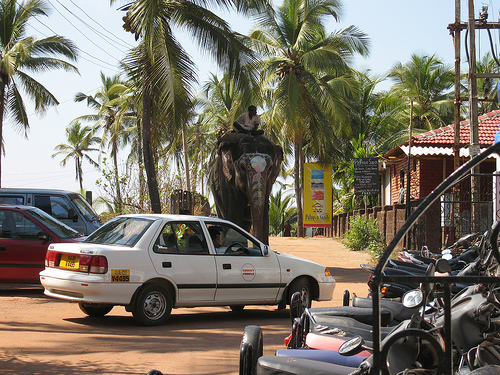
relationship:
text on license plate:
[63, 259, 77, 269] [57, 255, 81, 269]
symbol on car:
[238, 257, 260, 283] [48, 211, 340, 324]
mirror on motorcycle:
[399, 286, 434, 319] [224, 249, 472, 369]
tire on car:
[133, 281, 178, 328] [24, 205, 346, 333]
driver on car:
[204, 225, 235, 252] [48, 211, 340, 324]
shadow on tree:
[145, 320, 235, 370] [333, 250, 363, 282]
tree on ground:
[333, 250, 363, 282] [16, 320, 131, 363]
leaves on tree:
[311, 77, 353, 113] [118, 42, 209, 199]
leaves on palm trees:
[223, 55, 257, 95] [115, 0, 245, 215]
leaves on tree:
[324, 92, 352, 112] [249, 70, 369, 161]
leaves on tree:
[329, 75, 360, 113] [266, 14, 376, 161]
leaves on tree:
[294, 73, 346, 111] [239, 4, 374, 165]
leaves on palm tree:
[94, 79, 132, 126] [80, 72, 144, 218]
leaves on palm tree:
[71, 124, 96, 156] [48, 111, 98, 210]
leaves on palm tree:
[67, 129, 92, 147] [56, 110, 102, 194]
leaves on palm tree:
[415, 76, 437, 105] [384, 46, 458, 196]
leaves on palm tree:
[411, 64, 446, 87] [392, 47, 457, 127]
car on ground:
[34, 208, 346, 319] [0, 284, 311, 375]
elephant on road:
[205, 123, 279, 253] [276, 226, 397, 309]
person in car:
[208, 226, 236, 251] [34, 208, 346, 319]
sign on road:
[305, 159, 333, 223] [264, 217, 381, 302]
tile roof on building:
[412, 110, 499, 141] [376, 110, 494, 245]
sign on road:
[305, 159, 333, 223] [276, 226, 397, 309]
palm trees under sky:
[5, 1, 475, 245] [3, 2, 499, 193]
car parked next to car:
[0, 188, 106, 237] [5, 204, 85, 288]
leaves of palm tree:
[71, 130, 90, 151] [60, 110, 101, 195]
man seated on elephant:
[230, 105, 267, 134] [198, 123, 290, 251]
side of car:
[38, 210, 349, 322] [22, 187, 358, 327]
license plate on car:
[51, 251, 103, 278] [8, 185, 347, 331]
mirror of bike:
[329, 330, 369, 360] [190, 371, 484, 372]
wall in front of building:
[337, 134, 440, 251] [334, 89, 497, 271]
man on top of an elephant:
[219, 97, 295, 147] [190, 91, 310, 267]